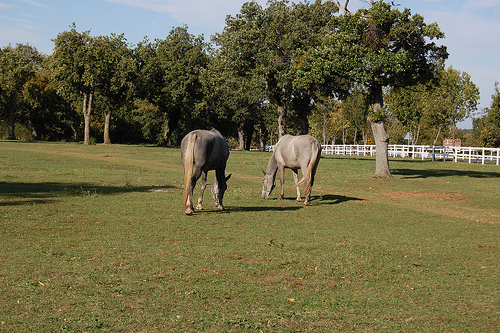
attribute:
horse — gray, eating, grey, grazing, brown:
[257, 134, 323, 204]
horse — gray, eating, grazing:
[177, 124, 233, 219]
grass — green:
[3, 144, 94, 218]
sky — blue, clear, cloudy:
[0, 1, 498, 64]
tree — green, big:
[51, 22, 117, 144]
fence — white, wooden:
[392, 140, 499, 164]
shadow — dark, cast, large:
[2, 168, 178, 209]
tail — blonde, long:
[306, 138, 321, 190]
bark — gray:
[377, 144, 384, 158]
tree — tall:
[216, 5, 337, 161]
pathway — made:
[318, 182, 427, 209]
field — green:
[2, 139, 499, 332]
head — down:
[257, 171, 278, 202]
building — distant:
[441, 134, 464, 155]